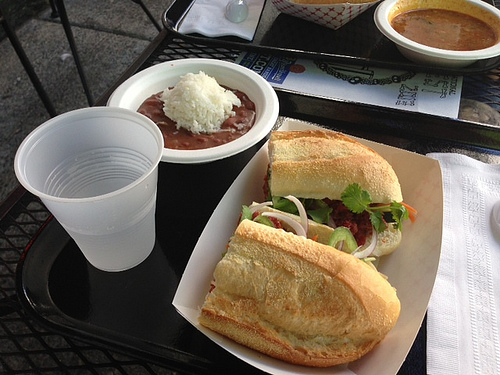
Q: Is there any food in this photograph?
A: Yes, there is food.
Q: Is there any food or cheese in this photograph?
A: Yes, there is food.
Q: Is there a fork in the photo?
A: No, there are no forks.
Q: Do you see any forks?
A: No, there are no forks.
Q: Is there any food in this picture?
A: Yes, there is food.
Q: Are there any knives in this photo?
A: No, there are no knives.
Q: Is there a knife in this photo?
A: No, there are no knives.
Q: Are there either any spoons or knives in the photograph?
A: No, there are no knives or spoons.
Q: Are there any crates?
A: No, there are no crates.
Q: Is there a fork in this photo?
A: No, there are no forks.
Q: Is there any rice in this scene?
A: Yes, there is rice.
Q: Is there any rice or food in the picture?
A: Yes, there is rice.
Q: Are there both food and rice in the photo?
A: Yes, there are both rice and food.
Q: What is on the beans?
A: The rice is on the beans.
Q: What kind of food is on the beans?
A: The food is rice.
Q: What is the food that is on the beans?
A: The food is rice.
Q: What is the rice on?
A: The rice is on the beans.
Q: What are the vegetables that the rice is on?
A: The vegetables are beans.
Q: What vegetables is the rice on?
A: The rice is on the beans.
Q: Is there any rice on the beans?
A: Yes, there is rice on the beans.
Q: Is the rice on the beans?
A: Yes, the rice is on the beans.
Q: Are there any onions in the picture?
A: Yes, there is an onion.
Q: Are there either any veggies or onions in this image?
A: Yes, there is an onion.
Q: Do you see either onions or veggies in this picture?
A: Yes, there is an onion.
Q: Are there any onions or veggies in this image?
A: Yes, there is an onion.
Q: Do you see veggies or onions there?
A: Yes, there is an onion.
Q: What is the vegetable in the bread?
A: The vegetable is an onion.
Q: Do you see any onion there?
A: Yes, there is an onion.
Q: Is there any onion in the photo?
A: Yes, there is an onion.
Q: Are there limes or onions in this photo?
A: Yes, there is an onion.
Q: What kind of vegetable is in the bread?
A: The vegetable is an onion.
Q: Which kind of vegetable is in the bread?
A: The vegetable is an onion.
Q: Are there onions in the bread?
A: Yes, there is an onion in the bread.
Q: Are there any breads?
A: Yes, there is a bread.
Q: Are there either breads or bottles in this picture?
A: Yes, there is a bread.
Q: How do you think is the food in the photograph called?
A: The food is a bread.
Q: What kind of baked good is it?
A: The food is a bread.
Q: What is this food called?
A: This is a bread.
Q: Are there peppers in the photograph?
A: Yes, there is a pepper.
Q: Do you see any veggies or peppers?
A: Yes, there is a pepper.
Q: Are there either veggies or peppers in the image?
A: Yes, there is a pepper.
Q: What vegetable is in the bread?
A: The vegetable is a pepper.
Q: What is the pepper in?
A: The pepper is in the bread.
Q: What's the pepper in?
A: The pepper is in the bread.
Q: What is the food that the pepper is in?
A: The food is a bread.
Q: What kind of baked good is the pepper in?
A: The pepper is in the bread.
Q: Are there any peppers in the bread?
A: Yes, there is a pepper in the bread.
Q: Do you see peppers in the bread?
A: Yes, there is a pepper in the bread.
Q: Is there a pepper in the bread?
A: Yes, there is a pepper in the bread.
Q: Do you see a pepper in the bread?
A: Yes, there is a pepper in the bread.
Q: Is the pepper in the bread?
A: Yes, the pepper is in the bread.